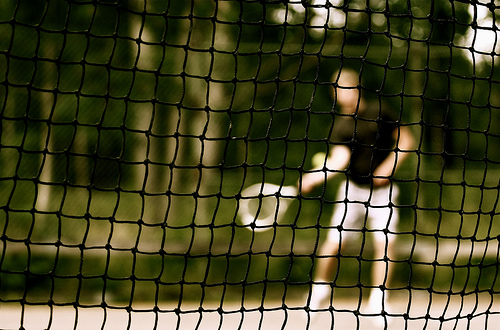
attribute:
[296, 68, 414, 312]
player — playing tennis, blurry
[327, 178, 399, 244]
shorts — white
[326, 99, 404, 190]
shirt — black, brown, polo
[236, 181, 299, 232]
tennis racket — white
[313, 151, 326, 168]
tennis ball — airborne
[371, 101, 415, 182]
left arm — bent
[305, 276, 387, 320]
shoes — white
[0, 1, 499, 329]
fence — in foreground, black, nylon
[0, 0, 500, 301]
trees — green, grouped, blurry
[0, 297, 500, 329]
tennis court — brown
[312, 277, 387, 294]
socks — white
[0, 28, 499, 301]
fence — chain-link